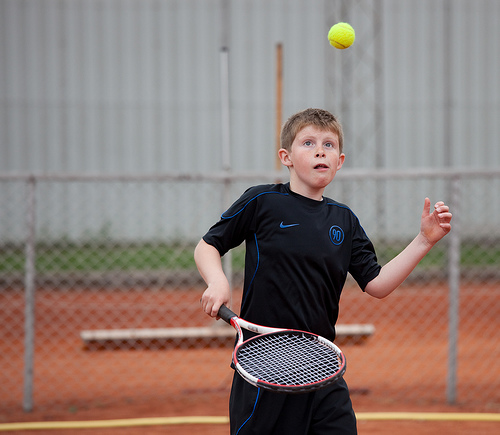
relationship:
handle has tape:
[219, 303, 268, 342] [217, 305, 234, 322]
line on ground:
[1, 410, 497, 431] [1, 278, 498, 432]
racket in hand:
[218, 305, 346, 394] [199, 282, 233, 320]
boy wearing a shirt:
[193, 108, 451, 433] [200, 183, 380, 377]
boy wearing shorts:
[193, 108, 451, 433] [230, 361, 358, 433]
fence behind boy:
[0, 164, 497, 411] [193, 108, 451, 433]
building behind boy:
[0, 0, 497, 242] [193, 108, 451, 433]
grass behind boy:
[0, 235, 497, 271] [193, 108, 451, 433]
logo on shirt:
[276, 218, 300, 232] [200, 183, 380, 377]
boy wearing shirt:
[193, 108, 451, 433] [200, 183, 380, 377]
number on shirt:
[326, 223, 348, 244] [200, 183, 380, 377]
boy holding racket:
[193, 108, 451, 433] [218, 305, 346, 394]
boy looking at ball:
[193, 108, 451, 433] [328, 19, 356, 51]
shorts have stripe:
[230, 361, 358, 433] [232, 386, 261, 433]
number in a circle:
[326, 223, 348, 244] [326, 224, 345, 246]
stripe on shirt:
[242, 230, 263, 312] [200, 183, 380, 377]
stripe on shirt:
[218, 187, 292, 223] [200, 183, 380, 377]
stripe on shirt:
[318, 199, 348, 215] [200, 183, 380, 377]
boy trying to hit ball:
[193, 108, 451, 433] [328, 19, 356, 51]